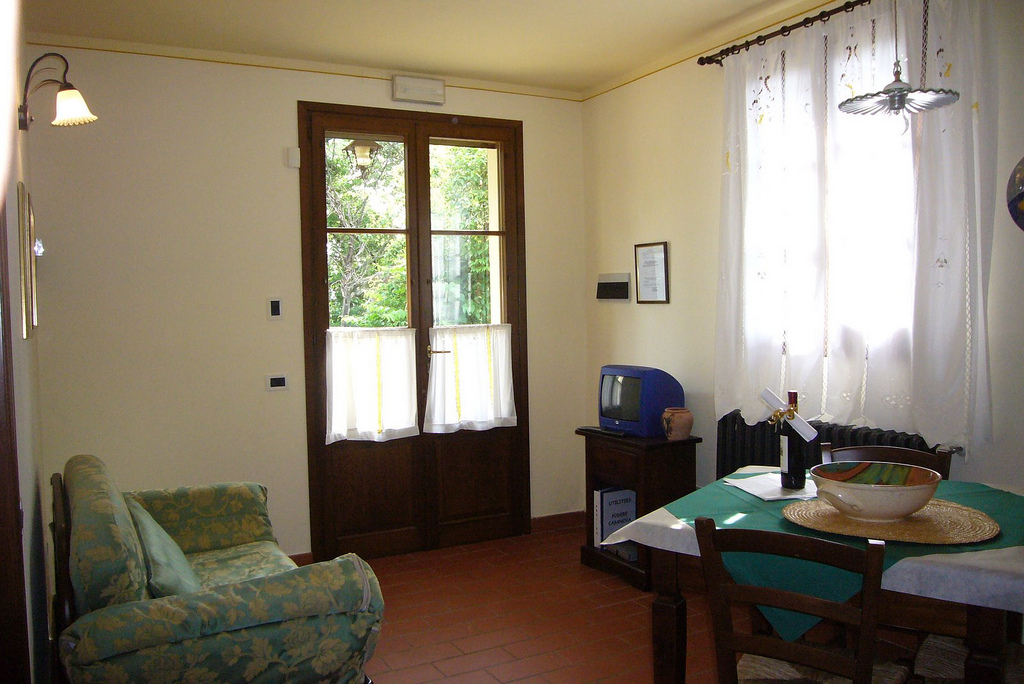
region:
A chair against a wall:
[43, 437, 383, 681]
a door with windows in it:
[287, 86, 547, 558]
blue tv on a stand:
[591, 354, 686, 450]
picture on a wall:
[631, 235, 671, 306]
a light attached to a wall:
[19, 47, 97, 136]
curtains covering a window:
[713, 22, 1020, 455]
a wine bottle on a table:
[771, 383, 810, 495]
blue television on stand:
[583, 356, 673, 439]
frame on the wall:
[627, 234, 679, 311]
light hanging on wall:
[46, 78, 108, 142]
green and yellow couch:
[36, 446, 398, 680]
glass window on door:
[416, 139, 519, 327]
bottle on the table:
[767, 388, 818, 496]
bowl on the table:
[812, 445, 946, 522]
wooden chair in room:
[688, 508, 892, 680]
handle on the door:
[425, 341, 460, 358]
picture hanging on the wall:
[629, 233, 669, 309]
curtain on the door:
[322, 316, 529, 443]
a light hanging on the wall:
[19, 41, 95, 140]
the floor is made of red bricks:
[310, 541, 734, 679]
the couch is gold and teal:
[42, 470, 381, 679]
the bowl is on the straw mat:
[785, 458, 1000, 556]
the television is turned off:
[593, 364, 688, 440]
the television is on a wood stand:
[567, 361, 697, 584]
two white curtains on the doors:
[314, 279, 531, 436]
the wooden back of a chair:
[690, 514, 893, 680]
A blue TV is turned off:
[580, 354, 701, 454]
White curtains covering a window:
[687, 0, 1001, 463]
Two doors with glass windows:
[285, 83, 543, 565]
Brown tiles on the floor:
[356, 506, 758, 674]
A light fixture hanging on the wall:
[8, 42, 104, 153]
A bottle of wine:
[754, 365, 832, 502]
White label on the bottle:
[760, 422, 805, 483]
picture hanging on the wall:
[628, 234, 677, 302]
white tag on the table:
[783, 408, 821, 443]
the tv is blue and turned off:
[596, 361, 682, 441]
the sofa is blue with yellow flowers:
[42, 451, 382, 682]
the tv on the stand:
[573, 361, 700, 590]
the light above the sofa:
[17, 48, 382, 681]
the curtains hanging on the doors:
[294, 97, 533, 568]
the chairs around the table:
[599, 389, 1021, 680]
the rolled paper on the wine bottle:
[753, 385, 818, 484]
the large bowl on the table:
[592, 459, 1022, 681]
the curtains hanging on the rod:
[696, 2, 997, 461]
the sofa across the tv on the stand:
[48, 361, 700, 681]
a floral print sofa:
[50, 414, 402, 675]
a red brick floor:
[374, 504, 622, 679]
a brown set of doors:
[270, 77, 587, 578]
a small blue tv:
[580, 335, 699, 465]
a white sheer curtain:
[692, 14, 1006, 468]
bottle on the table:
[764, 380, 818, 499]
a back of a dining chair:
[663, 500, 875, 679]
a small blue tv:
[596, 361, 683, 441]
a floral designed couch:
[51, 449, 390, 681]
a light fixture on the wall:
[15, 48, 96, 143]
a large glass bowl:
[812, 458, 946, 526]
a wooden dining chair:
[692, 506, 892, 680]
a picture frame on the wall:
[628, 240, 682, 311]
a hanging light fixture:
[837, 0, 962, 133]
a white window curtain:
[713, 2, 1023, 452]